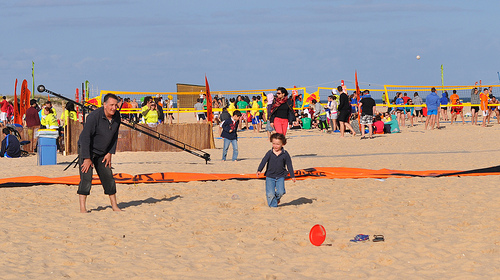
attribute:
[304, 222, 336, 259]
frisbee — red, rolling, round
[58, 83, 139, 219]
man — standing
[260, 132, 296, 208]
boy — small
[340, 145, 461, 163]
beach — busy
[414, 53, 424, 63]
volleyball — high, white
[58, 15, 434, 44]
sky — hazy, blue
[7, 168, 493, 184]
banner — orange, collapsed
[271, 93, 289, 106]
scarf — red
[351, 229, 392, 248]
flipflops — blue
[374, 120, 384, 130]
shirt — red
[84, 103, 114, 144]
shirt — black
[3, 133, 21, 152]
shirt — blue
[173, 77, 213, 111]
building — wood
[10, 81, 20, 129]
flag — orange, large, red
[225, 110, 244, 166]
child — young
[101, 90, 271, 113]
net — long, yellow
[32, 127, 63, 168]
trashcan — blue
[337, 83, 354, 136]
man — walking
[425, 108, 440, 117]
shorts — blue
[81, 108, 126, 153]
sweater — grey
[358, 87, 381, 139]
person — standing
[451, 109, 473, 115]
shorts — red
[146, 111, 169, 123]
shirt — yellow